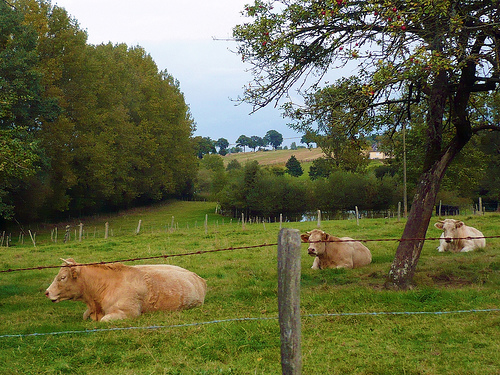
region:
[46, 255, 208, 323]
a light brown cow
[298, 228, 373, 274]
a light brown cow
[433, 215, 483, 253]
a light brown cow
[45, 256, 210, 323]
a cow laying in field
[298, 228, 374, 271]
a cow laying in field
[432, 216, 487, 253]
a cow laying in field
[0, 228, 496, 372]
a barbed wire fence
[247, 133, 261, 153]
large green tree in distance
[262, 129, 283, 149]
large green tree in distance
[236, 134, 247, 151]
large green tree in distance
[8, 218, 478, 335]
three cows in a line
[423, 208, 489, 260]
cow in the back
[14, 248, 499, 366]
lawn cows rest on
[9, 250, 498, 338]
fence to enclose cows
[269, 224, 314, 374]
post to support fence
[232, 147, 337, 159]
elevated terrain in distance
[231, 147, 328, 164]
brown and yellow grass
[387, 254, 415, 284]
shading on trunk of tree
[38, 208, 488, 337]
group of three cows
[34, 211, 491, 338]
cows laying on the grass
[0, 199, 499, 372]
green grass on the ground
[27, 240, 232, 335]
side profile of a cow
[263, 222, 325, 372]
wooden post on the fence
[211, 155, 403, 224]
dark green bushes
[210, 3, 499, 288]
tree is leaning to the right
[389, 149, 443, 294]
brown bark on the tree trunk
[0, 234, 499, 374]
two wires on the fence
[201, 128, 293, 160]
trees in the distance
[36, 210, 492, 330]
Three cows in a grassy pasture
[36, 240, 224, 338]
brown cow laying in grass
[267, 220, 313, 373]
brown wooden fence post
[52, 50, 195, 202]
tree covered in green leaves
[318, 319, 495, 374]
green grass growing on the ground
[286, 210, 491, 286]
two trees laying under tree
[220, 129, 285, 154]
row of trees on hill side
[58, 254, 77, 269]
small white horn on cow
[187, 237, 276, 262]
rusted barb wire fencing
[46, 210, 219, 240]
row of fencing on edge of field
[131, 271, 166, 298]
brown fur on side of cow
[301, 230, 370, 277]
A brown cow laying down.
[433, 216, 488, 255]
A brown cow laying down.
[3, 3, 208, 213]
two large bushy trees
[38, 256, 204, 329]
cow lying on the ground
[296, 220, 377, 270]
a brown sturdy cow